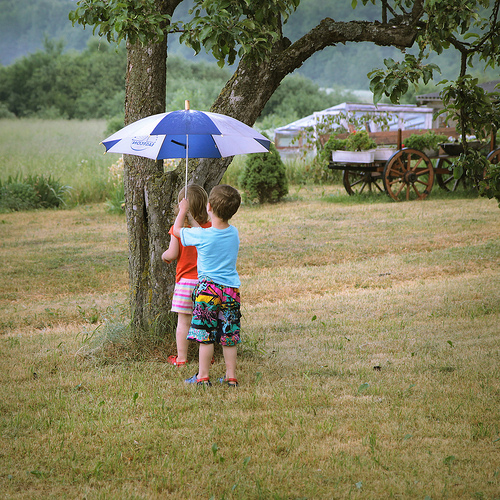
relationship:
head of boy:
[207, 185, 240, 217] [173, 181, 242, 388]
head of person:
[170, 182, 209, 235] [177, 181, 254, 397]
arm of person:
[170, 197, 200, 246] [187, 178, 272, 397]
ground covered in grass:
[17, 322, 475, 499] [1, 180, 498, 497]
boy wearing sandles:
[173, 181, 242, 388] [182, 372, 238, 386]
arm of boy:
[170, 197, 200, 247] [173, 181, 242, 388]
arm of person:
[159, 235, 183, 267] [160, 180, 214, 367]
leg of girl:
[169, 314, 193, 371] [161, 182, 216, 365]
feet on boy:
[185, 372, 212, 387] [173, 181, 242, 388]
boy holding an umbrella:
[173, 181, 242, 388] [100, 100, 272, 193]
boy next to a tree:
[173, 181, 242, 388] [69, 0, 499, 351]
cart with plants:
[326, 120, 493, 201] [325, 134, 452, 161]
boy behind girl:
[178, 181, 251, 377] [161, 182, 211, 362]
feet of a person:
[192, 195, 238, 350] [184, 174, 269, 381]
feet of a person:
[174, 369, 243, 390] [177, 181, 254, 397]